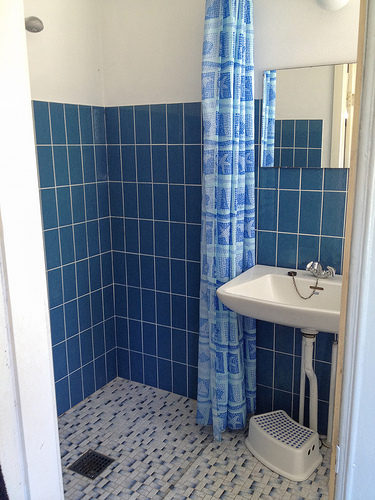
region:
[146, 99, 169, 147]
blue tile on the wall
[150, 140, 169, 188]
blue tile on the wall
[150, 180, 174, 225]
blue tile on the wall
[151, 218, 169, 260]
blue tile on the wall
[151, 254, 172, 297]
blue tile on the wall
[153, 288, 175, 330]
blue tile on the wall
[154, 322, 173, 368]
blue tile on the wall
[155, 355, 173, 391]
blue tile on the wall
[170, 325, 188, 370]
blue tile on the wall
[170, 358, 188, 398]
blue tile on the wall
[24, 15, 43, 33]
gray shower nozzle hanging on wall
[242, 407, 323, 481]
white step stool with non-slip surface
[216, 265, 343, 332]
white porcelain sink in small bathroom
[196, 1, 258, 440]
blue and white sea theme shower curtain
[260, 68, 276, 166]
reflection of shower curtain in mirror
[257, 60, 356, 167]
small rectangular mirror above bathroom sink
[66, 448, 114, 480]
dark gray drain in bottom of shower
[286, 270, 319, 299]
black sink plug on short chain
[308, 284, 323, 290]
thin rectangular overflow opening in sink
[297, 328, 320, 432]
exposed PVC pipes under sink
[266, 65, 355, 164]
a mirror on the back of the wall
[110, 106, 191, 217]
several blue tiles on wall with grout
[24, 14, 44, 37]
a round and silver shower head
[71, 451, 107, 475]
drain unit on bottom of shower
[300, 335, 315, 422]
white pipes connected to the sink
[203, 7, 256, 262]
large portion of blue shower curtain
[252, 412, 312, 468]
a white and blue step stool under sink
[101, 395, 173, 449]
blue and white tiles on shower floor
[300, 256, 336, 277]
faucet and knobs on bathroom sink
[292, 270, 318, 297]
the sink stopper with chain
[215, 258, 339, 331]
white porcelain hand sink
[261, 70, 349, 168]
mirror hanging on bathroom wall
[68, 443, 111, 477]
bathroom shower drain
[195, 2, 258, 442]
blue shower curtain hanging in bathroom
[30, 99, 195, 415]
blue ceramic tile wall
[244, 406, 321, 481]
small white sink step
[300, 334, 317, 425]
white sink tubes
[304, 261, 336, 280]
silver sink faucet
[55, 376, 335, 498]
blue and white ceramic tile bathroom floor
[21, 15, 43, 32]
grey shower head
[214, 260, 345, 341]
a white ceramic sink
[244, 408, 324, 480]
a plastic stool under the sink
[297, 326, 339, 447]
pipes under the sink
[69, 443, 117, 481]
a drain on the floor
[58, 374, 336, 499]
blue and white tile on the floor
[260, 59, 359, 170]
a mirror above the sink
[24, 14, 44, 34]
a shower head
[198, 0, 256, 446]
a blue shower curtain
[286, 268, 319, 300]
a chain hanging from the faucet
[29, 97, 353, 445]
blue tile on the walls